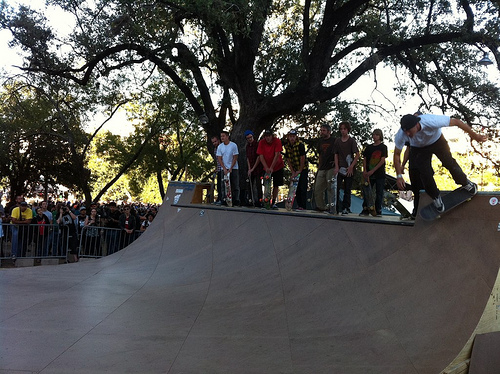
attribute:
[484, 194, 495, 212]
mark — white, spotted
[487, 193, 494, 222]
mark — white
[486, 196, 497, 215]
mark — white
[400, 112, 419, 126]
hat — black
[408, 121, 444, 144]
shirt — white, short sleeve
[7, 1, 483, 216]
tree — big